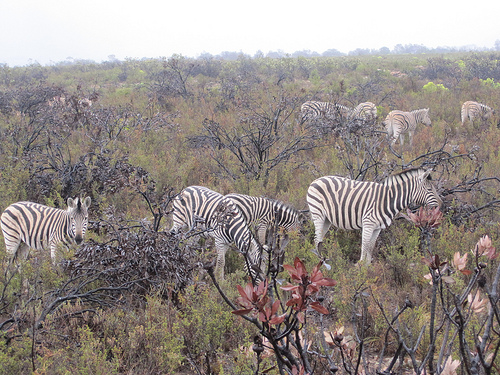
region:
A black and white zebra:
[292, 155, 458, 262]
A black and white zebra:
[163, 193, 253, 285]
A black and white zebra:
[235, 178, 315, 248]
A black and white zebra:
[4, 196, 111, 278]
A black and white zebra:
[288, 92, 352, 154]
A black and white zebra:
[352, 94, 384, 144]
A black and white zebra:
[386, 98, 445, 146]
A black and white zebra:
[445, 88, 495, 129]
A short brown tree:
[57, 248, 193, 374]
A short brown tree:
[212, 223, 349, 374]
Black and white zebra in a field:
[308, 162, 453, 257]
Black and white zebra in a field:
[165, 170, 274, 307]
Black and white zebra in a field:
[226, 171, 318, 280]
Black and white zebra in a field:
[0, 187, 97, 269]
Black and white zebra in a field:
[301, 82, 338, 152]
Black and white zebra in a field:
[347, 91, 382, 154]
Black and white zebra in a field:
[387, 84, 424, 150]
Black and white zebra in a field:
[453, 91, 496, 155]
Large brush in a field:
[30, 141, 150, 192]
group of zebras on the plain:
[0, 95, 492, 264]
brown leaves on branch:
[230, 251, 332, 335]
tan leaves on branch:
[452, 235, 494, 274]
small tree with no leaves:
[206, 108, 323, 191]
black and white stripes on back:
[312, 176, 376, 223]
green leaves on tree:
[419, 78, 449, 95]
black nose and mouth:
[72, 230, 83, 244]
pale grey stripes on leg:
[360, 228, 371, 261]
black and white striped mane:
[383, 167, 426, 187]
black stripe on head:
[75, 197, 81, 213]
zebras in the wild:
[8, 85, 498, 329]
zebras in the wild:
[34, 79, 488, 344]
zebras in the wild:
[5, 85, 492, 352]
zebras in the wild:
[28, 82, 478, 362]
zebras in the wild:
[2, 70, 499, 328]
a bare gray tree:
[191, 93, 331, 203]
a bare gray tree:
[205, 67, 305, 194]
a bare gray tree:
[176, 91, 304, 204]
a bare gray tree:
[176, 82, 308, 194]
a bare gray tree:
[162, 71, 337, 213]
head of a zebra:
[413, 169, 454, 207]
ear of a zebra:
[419, 149, 440, 187]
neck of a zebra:
[379, 169, 426, 217]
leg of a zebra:
[339, 226, 393, 278]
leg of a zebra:
[286, 211, 346, 296]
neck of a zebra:
[249, 208, 304, 250]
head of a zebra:
[57, 181, 119, 262]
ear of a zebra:
[63, 185, 80, 213]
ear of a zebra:
[83, 201, 104, 218]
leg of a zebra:
[213, 245, 247, 297]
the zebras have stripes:
[0, 164, 441, 286]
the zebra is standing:
[306, 163, 442, 265]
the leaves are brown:
[231, 256, 337, 373]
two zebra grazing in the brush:
[172, 184, 309, 276]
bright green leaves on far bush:
[421, 80, 457, 96]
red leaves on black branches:
[234, 256, 339, 336]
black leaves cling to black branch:
[41, 192, 229, 317]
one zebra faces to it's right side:
[1, 190, 93, 267]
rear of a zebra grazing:
[458, 93, 498, 130]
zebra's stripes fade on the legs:
[354, 212, 381, 261]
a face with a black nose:
[67, 199, 90, 247]